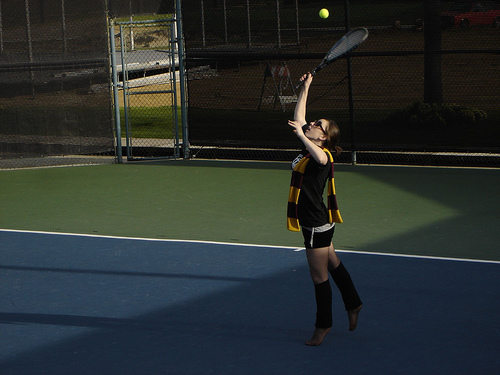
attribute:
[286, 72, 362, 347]
woman — tip toe, practicing, tip toed, white, brunette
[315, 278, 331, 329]
leg warmer — black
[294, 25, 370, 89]
racquet — black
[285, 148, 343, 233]
scarf — striped, stripes, gold, black, yellow, brown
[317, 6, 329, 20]
tennis ball — yellow, mid air, yellow green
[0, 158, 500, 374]
tennis court — blue, green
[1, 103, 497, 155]
grass — green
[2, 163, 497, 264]
outside court — green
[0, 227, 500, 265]
line — white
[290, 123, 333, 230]
shirt — black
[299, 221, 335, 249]
shorts — black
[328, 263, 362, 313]
leg warmer — black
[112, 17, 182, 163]
entrance — metal